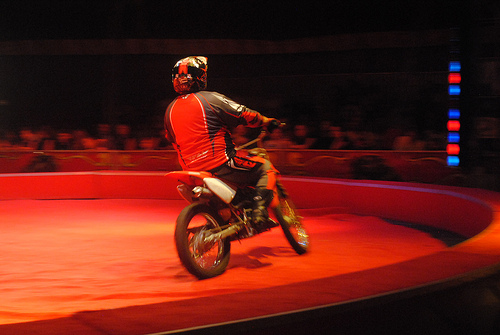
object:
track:
[2, 177, 499, 329]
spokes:
[196, 245, 208, 269]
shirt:
[161, 90, 266, 172]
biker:
[162, 56, 281, 228]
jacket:
[162, 90, 267, 179]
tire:
[274, 194, 310, 254]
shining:
[0, 208, 164, 265]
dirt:
[55, 237, 122, 293]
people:
[287, 124, 315, 148]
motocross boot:
[246, 188, 270, 235]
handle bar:
[257, 128, 276, 136]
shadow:
[230, 248, 272, 270]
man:
[19, 128, 52, 151]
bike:
[165, 123, 310, 279]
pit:
[0, 171, 500, 335]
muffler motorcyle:
[165, 170, 212, 206]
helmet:
[172, 56, 208, 94]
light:
[449, 62, 461, 72]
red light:
[449, 72, 461, 84]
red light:
[445, 118, 461, 130]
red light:
[447, 144, 460, 155]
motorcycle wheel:
[174, 205, 231, 278]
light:
[447, 154, 460, 166]